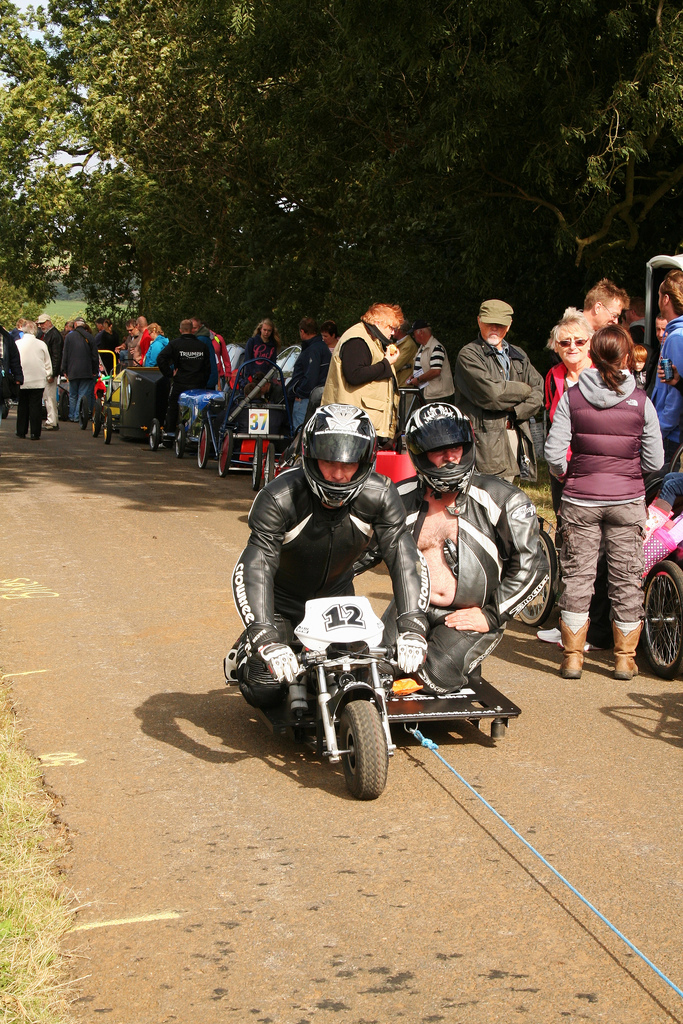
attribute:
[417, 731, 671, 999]
cord — blue 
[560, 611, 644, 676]
boots — brown , cowboy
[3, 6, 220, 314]
trees — tall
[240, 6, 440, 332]
trees — tall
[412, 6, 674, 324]
trees — tall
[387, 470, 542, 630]
jacket — open, leather 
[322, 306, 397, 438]
person — red haired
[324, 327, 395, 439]
vest — brown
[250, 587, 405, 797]
motorcycle — small, white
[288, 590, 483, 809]
motorcycle — white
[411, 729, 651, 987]
rope — blue, large, thin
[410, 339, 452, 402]
shirt — black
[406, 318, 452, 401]
man — white, striped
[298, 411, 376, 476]
helmet — black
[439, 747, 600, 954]
rope — blue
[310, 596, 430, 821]
bike — small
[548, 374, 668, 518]
coat — purple, silver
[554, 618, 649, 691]
boots — brown, leather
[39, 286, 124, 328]
grass — green